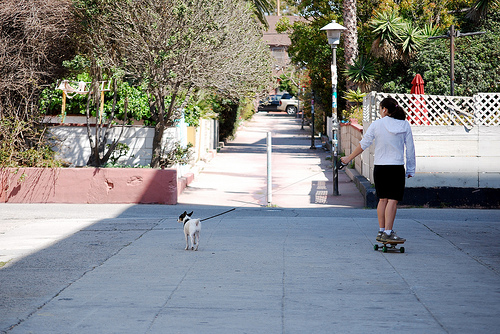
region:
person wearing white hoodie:
[335, 81, 421, 250]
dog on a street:
[174, 195, 201, 249]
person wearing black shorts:
[340, 86, 430, 259]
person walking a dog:
[146, 41, 431, 268]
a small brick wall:
[5, 150, 182, 210]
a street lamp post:
[318, 13, 345, 202]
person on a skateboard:
[322, 90, 434, 259]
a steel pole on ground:
[253, 125, 283, 205]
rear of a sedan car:
[275, 80, 305, 115]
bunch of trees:
[322, 6, 497, 88]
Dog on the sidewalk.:
[159, 177, 209, 257]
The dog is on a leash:
[166, 148, 356, 245]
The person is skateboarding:
[351, 89, 425, 261]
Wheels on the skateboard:
[371, 240, 406, 253]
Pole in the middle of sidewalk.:
[240, 114, 281, 208]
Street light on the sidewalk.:
[303, 20, 340, 261]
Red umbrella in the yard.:
[397, 65, 431, 134]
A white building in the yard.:
[48, 103, 188, 168]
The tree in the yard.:
[18, 27, 258, 122]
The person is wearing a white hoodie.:
[348, 118, 428, 163]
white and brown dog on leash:
[178, 209, 203, 253]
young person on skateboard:
[327, 98, 417, 257]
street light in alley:
[317, 18, 349, 195]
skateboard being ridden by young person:
[371, 233, 404, 254]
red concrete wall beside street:
[1, 166, 186, 207]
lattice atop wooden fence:
[376, 90, 497, 130]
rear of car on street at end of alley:
[278, 93, 307, 116]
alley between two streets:
[181, 109, 363, 209]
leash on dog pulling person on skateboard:
[196, 160, 346, 221]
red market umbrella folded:
[406, 71, 428, 125]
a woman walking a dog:
[175, 89, 412, 263]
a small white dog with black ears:
[172, 211, 209, 251]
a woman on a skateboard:
[357, 95, 420, 258]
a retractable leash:
[192, 159, 351, 222]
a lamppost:
[323, 18, 351, 200]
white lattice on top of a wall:
[360, 92, 498, 127]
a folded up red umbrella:
[404, 75, 431, 127]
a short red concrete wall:
[0, 169, 177, 205]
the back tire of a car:
[285, 104, 297, 116]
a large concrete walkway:
[181, 109, 363, 214]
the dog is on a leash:
[145, 203, 315, 283]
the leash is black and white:
[159, 173, 347, 318]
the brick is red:
[44, 164, 149, 233]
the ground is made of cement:
[47, 232, 264, 326]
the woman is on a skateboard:
[308, 98, 460, 325]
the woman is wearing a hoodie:
[347, 101, 492, 223]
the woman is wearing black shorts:
[360, 165, 498, 229]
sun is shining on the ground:
[200, 135, 433, 265]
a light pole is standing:
[321, 21, 376, 103]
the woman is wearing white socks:
[368, 217, 445, 264]